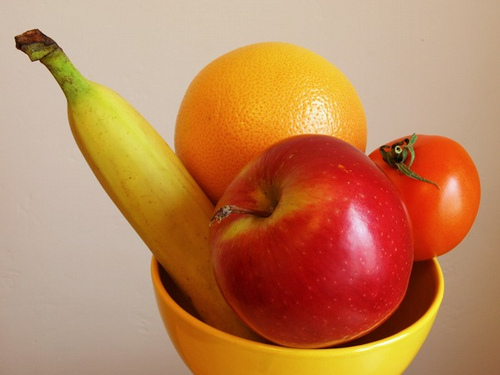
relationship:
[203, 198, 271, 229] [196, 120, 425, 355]
stem on apple